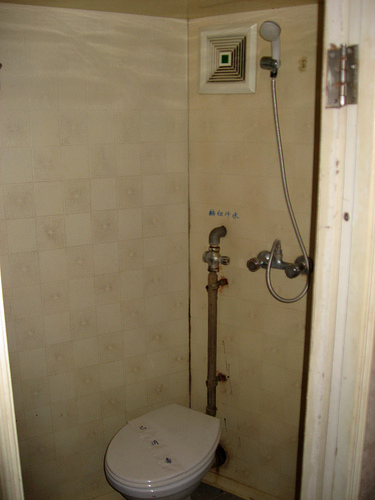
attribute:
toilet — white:
[84, 335, 240, 497]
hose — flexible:
[257, 94, 321, 233]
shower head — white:
[259, 19, 285, 79]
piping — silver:
[264, 78, 311, 308]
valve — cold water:
[284, 255, 315, 282]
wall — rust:
[45, 89, 118, 154]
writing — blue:
[183, 206, 260, 231]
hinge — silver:
[321, 39, 365, 111]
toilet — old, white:
[104, 399, 223, 497]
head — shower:
[201, 10, 346, 321]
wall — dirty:
[19, 32, 173, 284]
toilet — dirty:
[91, 388, 249, 485]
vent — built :
[196, 22, 257, 92]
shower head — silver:
[257, 20, 282, 69]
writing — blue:
[139, 423, 175, 468]